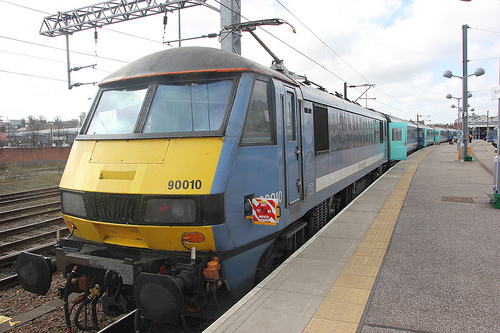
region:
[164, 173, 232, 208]
Black numbers on front of train.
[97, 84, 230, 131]
Large windshield on front of train.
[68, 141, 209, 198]
Front section of train is yellow.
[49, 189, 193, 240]
Lights on front of train.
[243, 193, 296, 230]
Red and white sign on side of train.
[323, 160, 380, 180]
White stripe on side of train.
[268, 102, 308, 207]
Blue door on side of train.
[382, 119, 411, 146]
Door is open on train.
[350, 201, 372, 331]
Sidewalk has yellow stripe on platform.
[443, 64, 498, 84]
Lights on silver pole.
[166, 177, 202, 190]
The number 90010 in black letters on a train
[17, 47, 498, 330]
A primarily blue train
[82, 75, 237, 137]
The front windshield of the train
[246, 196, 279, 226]
A red and white sign on the train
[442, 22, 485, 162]
A row of light posts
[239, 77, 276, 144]
The most front left window of the train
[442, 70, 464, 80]
A light on the light post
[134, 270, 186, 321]
The left black bumper on the train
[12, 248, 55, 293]
The right black bumper of the train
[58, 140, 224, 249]
The yellow and black front of the train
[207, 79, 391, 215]
the train is blue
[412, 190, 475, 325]
the platform is paved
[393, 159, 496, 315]
the platform is paved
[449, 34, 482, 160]
the pole is gray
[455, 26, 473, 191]
the pole is gray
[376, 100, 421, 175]
train's door is open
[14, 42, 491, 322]
Train stopped at a station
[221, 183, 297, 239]
Sign flipped out representing "stop"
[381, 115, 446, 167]
Open doors on the train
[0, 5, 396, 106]
Electric power line guides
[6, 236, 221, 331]
Bumpers on front of train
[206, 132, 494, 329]
Passenger platform at train station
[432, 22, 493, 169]
Light posts on the platform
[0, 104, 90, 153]
Housing behind train station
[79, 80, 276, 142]
Windshield at front of train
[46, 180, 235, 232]
Headlights at the front of train